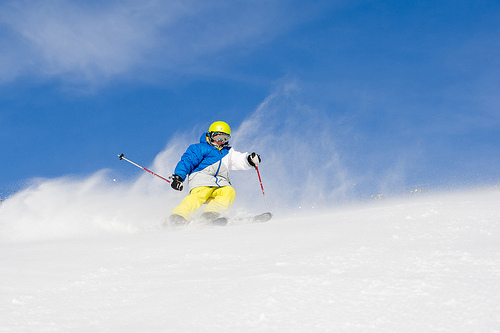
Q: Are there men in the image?
A: No, there are no men.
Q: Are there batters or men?
A: No, there are no men or batters.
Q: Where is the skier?
A: The skier is on the snow.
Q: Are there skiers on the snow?
A: Yes, there is a skier on the snow.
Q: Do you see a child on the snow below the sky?
A: No, there is a skier on the snow.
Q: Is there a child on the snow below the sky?
A: No, there is a skier on the snow.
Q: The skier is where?
A: The skier is in the snow.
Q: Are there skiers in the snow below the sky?
A: Yes, there is a skier in the snow.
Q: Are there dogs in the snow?
A: No, there is a skier in the snow.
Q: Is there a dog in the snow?
A: No, there is a skier in the snow.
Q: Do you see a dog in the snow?
A: No, there is a skier in the snow.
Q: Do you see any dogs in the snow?
A: No, there is a skier in the snow.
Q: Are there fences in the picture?
A: No, there are no fences.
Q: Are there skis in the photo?
A: Yes, there are skis.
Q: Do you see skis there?
A: Yes, there are skis.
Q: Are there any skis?
A: Yes, there are skis.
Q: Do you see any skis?
A: Yes, there are skis.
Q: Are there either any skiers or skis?
A: Yes, there are skis.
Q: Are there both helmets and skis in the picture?
A: Yes, there are both skis and a helmet.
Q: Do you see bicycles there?
A: No, there are no bicycles.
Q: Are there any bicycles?
A: No, there are no bicycles.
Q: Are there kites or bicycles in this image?
A: No, there are no bicycles or kites.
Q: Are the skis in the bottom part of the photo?
A: Yes, the skis are in the bottom of the image.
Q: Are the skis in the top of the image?
A: No, the skis are in the bottom of the image.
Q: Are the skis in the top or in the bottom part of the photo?
A: The skis are in the bottom of the image.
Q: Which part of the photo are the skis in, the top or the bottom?
A: The skis are in the bottom of the image.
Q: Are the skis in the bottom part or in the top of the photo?
A: The skis are in the bottom of the image.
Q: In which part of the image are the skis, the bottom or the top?
A: The skis are in the bottom of the image.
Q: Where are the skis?
A: The skis are in the snow.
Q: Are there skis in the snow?
A: Yes, there are skis in the snow.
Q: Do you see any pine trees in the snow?
A: No, there are skis in the snow.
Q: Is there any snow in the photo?
A: Yes, there is snow.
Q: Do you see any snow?
A: Yes, there is snow.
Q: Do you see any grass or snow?
A: Yes, there is snow.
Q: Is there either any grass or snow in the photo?
A: Yes, there is snow.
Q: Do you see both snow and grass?
A: No, there is snow but no grass.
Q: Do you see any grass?
A: No, there is no grass.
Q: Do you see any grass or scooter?
A: No, there are no grass or scooters.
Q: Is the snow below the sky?
A: Yes, the snow is below the sky.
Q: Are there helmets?
A: Yes, there is a helmet.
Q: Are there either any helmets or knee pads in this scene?
A: Yes, there is a helmet.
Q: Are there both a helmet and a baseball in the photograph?
A: No, there is a helmet but no baseballs.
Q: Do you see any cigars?
A: No, there are no cigars.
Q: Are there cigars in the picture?
A: No, there are no cigars.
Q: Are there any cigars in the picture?
A: No, there are no cigars.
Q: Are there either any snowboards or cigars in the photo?
A: No, there are no cigars or snowboards.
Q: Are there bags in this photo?
A: No, there are no bags.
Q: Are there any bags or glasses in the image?
A: No, there are no bags or glasses.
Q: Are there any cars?
A: No, there are no cars.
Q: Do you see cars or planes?
A: No, there are no cars or planes.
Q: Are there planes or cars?
A: No, there are no cars or planes.